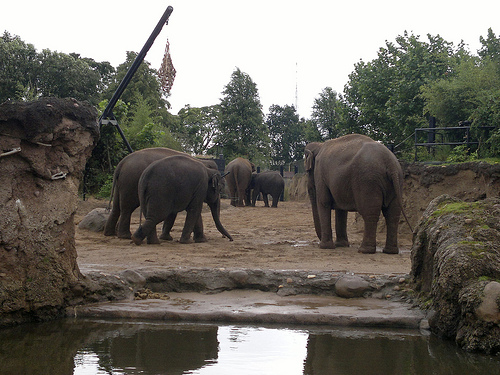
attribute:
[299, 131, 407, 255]
elephant — grey, standing, brown, big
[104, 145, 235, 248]
elephants — walking, together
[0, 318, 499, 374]
water — brown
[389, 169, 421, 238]
tail — long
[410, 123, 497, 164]
fence — black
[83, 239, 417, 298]
mud — brown, white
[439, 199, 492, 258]
grass — green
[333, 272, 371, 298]
rock — grey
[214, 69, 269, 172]
tree — green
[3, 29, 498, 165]
trees — green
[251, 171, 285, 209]
elephant — small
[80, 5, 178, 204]
pole — black